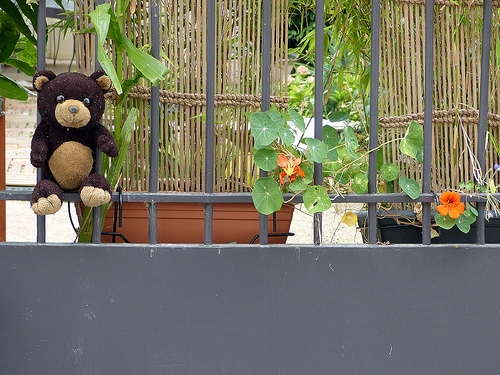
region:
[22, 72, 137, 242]
Teddy bear hanging on fence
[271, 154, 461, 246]
Orange flowers on the plant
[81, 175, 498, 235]
Two flower pots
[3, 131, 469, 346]
Gray fence in front of flower pots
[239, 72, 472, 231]
Green leaves on plant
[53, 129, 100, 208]
Teddy bear has light brown tummy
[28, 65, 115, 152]
Teddy bear has 2 eyes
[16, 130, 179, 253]
Teddy bear is sitting on fence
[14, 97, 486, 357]
Fence is metal and painted gray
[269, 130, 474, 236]
Two flowers on the plant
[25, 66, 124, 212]
teddy bear on a fence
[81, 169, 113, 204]
left leg of teddy bear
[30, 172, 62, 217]
right leg of teddy bear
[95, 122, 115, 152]
left arm of teddy bear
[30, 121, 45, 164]
right arm of teddy bear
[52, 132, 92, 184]
belly of teddy bear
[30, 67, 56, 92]
right ear of teddy bear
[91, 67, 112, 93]
left ear of teddy bear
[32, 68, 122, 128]
head of teddy bear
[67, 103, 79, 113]
nose of teddy bear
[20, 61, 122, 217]
brown stuffed bear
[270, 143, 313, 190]
orange petals on flower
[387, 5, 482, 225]
bamboo screen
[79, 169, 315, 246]
brick colored flower box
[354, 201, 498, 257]
black flower box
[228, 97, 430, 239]
plant with green leaves and orange flowers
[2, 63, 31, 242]
cream brick side wall of house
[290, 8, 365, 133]
green leaves on tree in the summer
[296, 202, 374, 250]
cement sidewalk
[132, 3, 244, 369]
gray security wall with bars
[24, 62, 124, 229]
stuffed bear on fence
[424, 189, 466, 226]
orange flower under rail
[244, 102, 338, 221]
green leaves surrounding flower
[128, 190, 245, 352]
gray wall under fence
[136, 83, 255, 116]
rope attached to wood sticks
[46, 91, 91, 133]
face on teddy bear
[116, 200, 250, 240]
clay pot behind fence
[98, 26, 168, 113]
leaves on tall plant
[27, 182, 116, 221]
feet on stuffed bear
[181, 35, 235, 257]
gray fence pole on wall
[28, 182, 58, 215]
right foot of a doll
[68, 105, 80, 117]
nose of the doll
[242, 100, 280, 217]
green leaves of a plant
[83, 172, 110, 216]
left leg of a doll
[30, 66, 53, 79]
right ear of a doll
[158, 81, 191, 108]
part of a thick rope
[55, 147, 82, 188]
stomach of a doll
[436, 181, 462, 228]
part of an orange flower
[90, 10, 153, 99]
green leaves of a nappier grass